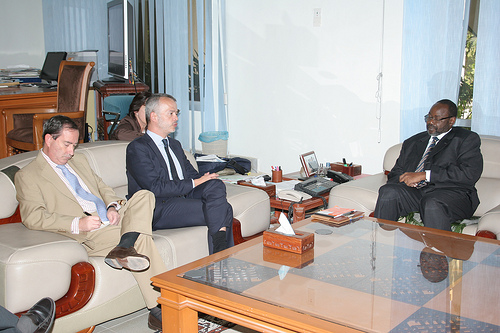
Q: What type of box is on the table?
A: Tissue.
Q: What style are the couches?
A: Leather.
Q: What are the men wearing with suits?
A: Ties.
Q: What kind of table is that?
A: A coffee table.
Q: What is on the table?
A: Tissues.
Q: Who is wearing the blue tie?
A: The man on the left.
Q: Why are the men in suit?
A: For a meeting.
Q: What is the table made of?
A: Woods.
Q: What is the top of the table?
A: Glass.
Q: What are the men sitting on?
A: Couches.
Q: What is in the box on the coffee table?
A: Kleenex.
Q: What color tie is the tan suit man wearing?
A: Blue.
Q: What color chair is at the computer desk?
A: Brown.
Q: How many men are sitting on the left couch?
A: Two.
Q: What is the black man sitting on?
A: Chair.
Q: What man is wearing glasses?
A: Black man.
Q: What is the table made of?
A: Wood and glass.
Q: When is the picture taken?
A: Daytime.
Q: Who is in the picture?
A: Buisnessmen.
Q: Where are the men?
A: In an office.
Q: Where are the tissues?
A: On the table.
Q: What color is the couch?
A: White.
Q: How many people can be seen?
A: 4.